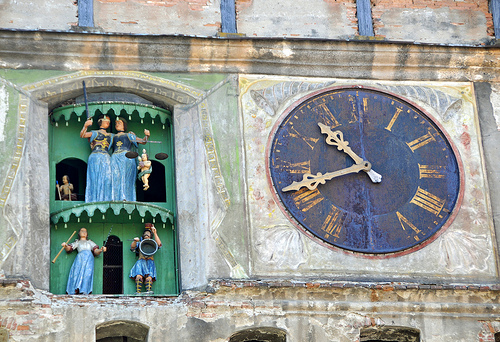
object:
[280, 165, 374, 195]
hand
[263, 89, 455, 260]
clock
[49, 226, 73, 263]
stick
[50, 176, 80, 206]
boy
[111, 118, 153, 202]
ladies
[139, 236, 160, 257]
shield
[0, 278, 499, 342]
wall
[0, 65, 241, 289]
scene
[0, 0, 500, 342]
building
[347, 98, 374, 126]
numerals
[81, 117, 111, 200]
people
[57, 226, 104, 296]
person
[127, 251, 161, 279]
robe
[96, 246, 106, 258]
drum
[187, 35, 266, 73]
paint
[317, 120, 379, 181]
pointer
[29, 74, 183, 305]
figurines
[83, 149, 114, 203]
outfits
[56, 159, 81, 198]
door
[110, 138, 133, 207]
man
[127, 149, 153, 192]
puppet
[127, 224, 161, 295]
statue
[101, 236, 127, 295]
windows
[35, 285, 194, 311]
display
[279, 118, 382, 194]
10:42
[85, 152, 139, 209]
blue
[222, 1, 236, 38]
stone